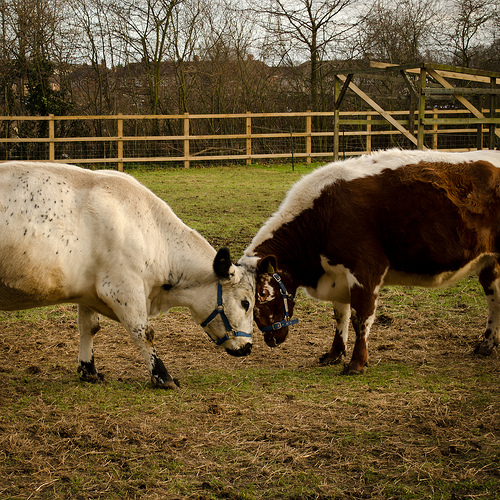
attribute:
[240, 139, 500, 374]
cow — brown, large, standing, white, black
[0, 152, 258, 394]
cow — white, large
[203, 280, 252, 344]
harness — blue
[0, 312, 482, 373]
hay — loose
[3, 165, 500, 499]
grass — green, dried, brown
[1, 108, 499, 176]
fence — made of wood, wooden, brown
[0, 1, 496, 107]
trees — bald, bare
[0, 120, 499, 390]
cows — pair, facing each other, butting heads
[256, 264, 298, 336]
muzzle — black, blue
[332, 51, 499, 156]
structure — wooden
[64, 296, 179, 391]
legs — white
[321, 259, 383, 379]
legs — spotted